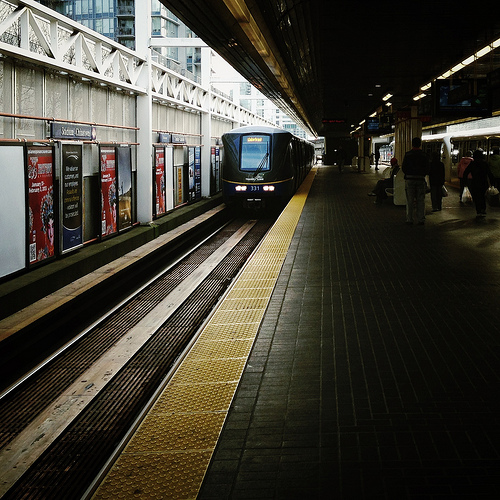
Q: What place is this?
A: It is a train station.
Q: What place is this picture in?
A: It is at the train station.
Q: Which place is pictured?
A: It is a train station.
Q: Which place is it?
A: It is a train station.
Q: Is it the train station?
A: Yes, it is the train station.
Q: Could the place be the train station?
A: Yes, it is the train station.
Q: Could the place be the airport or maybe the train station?
A: It is the train station.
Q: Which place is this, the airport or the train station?
A: It is the train station.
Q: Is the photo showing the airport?
A: No, the picture is showing the train station.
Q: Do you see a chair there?
A: No, there are no chairs.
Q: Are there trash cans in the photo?
A: No, there are no trash cans.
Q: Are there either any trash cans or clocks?
A: No, there are no trash cans or clocks.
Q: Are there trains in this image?
A: Yes, there is a train.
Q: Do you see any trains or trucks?
A: Yes, there is a train.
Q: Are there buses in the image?
A: No, there are no buses.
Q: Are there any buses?
A: No, there are no buses.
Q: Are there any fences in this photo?
A: No, there are no fences.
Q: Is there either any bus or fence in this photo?
A: No, there are no fences or buses.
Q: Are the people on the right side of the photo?
A: Yes, the people are on the right of the image.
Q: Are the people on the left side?
A: No, the people are on the right of the image.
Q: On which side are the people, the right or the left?
A: The people are on the right of the image.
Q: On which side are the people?
A: The people are on the right of the image.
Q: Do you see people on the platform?
A: Yes, there are people on the platform.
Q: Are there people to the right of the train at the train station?
A: Yes, there are people to the right of the train.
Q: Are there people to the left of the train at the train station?
A: No, the people are to the right of the train.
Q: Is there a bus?
A: No, there are no buses.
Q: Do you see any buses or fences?
A: No, there are no buses or fences.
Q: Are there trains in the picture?
A: Yes, there is a train.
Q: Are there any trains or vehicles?
A: Yes, there is a train.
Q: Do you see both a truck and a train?
A: No, there is a train but no trucks.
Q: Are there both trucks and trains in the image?
A: No, there is a train but no trucks.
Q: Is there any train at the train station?
A: Yes, there is a train at the train station.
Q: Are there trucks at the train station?
A: No, there is a train at the train station.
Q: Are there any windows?
A: Yes, there is a window.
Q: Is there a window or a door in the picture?
A: Yes, there is a window.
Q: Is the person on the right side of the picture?
A: Yes, the person is on the right of the image.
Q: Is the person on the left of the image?
A: No, the person is on the right of the image.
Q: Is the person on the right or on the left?
A: The person is on the right of the image.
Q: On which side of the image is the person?
A: The person is on the right of the image.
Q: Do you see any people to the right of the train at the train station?
A: Yes, there is a person to the right of the train.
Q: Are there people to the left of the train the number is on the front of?
A: No, the person is to the right of the train.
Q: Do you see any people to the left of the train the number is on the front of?
A: No, the person is to the right of the train.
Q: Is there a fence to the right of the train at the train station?
A: No, there is a person to the right of the train.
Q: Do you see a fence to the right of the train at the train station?
A: No, there is a person to the right of the train.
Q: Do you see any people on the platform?
A: Yes, there is a person on the platform.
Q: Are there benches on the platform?
A: No, there is a person on the platform.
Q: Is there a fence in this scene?
A: No, there are no fences.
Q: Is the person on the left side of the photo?
A: No, the person is on the right of the image.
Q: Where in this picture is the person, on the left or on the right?
A: The person is on the right of the image.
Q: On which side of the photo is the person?
A: The person is on the right of the image.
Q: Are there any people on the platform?
A: Yes, there is a person on the platform.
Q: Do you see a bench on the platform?
A: No, there is a person on the platform.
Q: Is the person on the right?
A: Yes, the person is on the right of the image.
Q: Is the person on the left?
A: No, the person is on the right of the image.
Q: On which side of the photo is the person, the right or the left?
A: The person is on the right of the image.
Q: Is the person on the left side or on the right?
A: The person is on the right of the image.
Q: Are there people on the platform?
A: Yes, there is a person on the platform.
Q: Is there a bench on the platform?
A: No, there is a person on the platform.